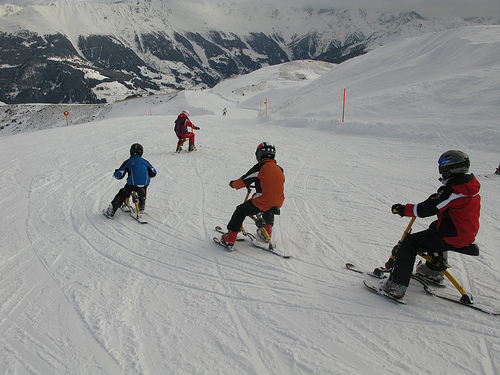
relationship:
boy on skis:
[379, 150, 481, 301] [346, 207, 499, 316]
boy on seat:
[379, 150, 481, 301] [439, 236, 479, 257]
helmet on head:
[130, 145, 145, 156] [127, 140, 141, 157]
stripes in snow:
[81, 129, 496, 339] [3, 7, 499, 374]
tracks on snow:
[95, 229, 204, 274] [13, 222, 209, 369]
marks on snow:
[93, 254, 339, 328] [3, 7, 499, 374]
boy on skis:
[232, 142, 301, 249] [210, 224, 300, 264]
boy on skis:
[345, 150, 497, 322] [337, 260, 498, 323]